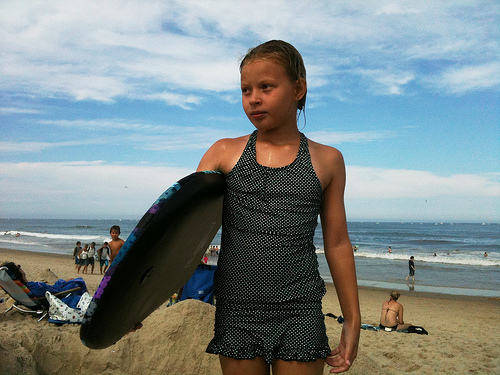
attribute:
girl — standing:
[130, 40, 362, 374]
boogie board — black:
[80, 170, 226, 350]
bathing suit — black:
[205, 130, 331, 365]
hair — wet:
[240, 40, 307, 131]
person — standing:
[406, 256, 417, 282]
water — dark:
[1, 218, 500, 290]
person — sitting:
[379, 291, 414, 331]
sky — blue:
[1, 1, 500, 225]